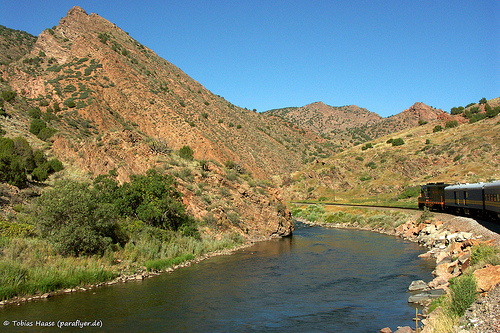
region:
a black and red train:
[407, 180, 449, 213]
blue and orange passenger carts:
[442, 183, 497, 213]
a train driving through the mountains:
[378, 175, 496, 220]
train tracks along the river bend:
[158, 190, 436, 330]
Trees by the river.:
[30, 158, 189, 260]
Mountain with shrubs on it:
[15, 5, 272, 171]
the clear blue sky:
[241, 20, 367, 78]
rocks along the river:
[404, 220, 482, 292]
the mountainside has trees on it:
[92, 53, 249, 203]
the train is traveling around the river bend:
[407, 175, 497, 230]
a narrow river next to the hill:
[23, 222, 431, 331]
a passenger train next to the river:
[415, 178, 499, 223]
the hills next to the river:
[5, 13, 446, 285]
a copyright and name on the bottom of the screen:
[1, 315, 111, 332]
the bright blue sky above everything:
[1, 0, 499, 111]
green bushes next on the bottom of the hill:
[3, 134, 198, 261]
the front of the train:
[414, 183, 449, 209]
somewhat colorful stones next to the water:
[416, 220, 494, 305]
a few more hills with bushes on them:
[283, 99, 490, 181]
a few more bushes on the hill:
[446, 96, 491, 123]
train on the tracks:
[412, 172, 499, 217]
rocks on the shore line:
[115, 264, 159, 285]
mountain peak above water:
[37, 1, 153, 53]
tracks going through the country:
[320, 194, 379, 214]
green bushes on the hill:
[370, 135, 414, 159]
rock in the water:
[403, 278, 429, 293]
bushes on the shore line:
[309, 209, 339, 222]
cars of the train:
[443, 181, 498, 215]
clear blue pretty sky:
[248, 58, 293, 74]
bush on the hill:
[176, 137, 196, 167]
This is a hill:
[33, 5, 170, 118]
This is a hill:
[255, 83, 383, 158]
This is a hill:
[386, 88, 448, 150]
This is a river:
[89, 199, 433, 325]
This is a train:
[411, 177, 498, 219]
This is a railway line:
[279, 189, 419, 221]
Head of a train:
[396, 178, 446, 214]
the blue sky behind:
[140, 0, 475, 101]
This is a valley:
[246, 105, 419, 244]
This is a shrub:
[30, 131, 220, 267]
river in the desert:
[3, 208, 427, 328]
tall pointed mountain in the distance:
[0, 8, 292, 195]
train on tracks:
[420, 182, 499, 222]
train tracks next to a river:
[285, 199, 498, 254]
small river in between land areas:
[0, 207, 439, 328]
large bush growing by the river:
[34, 167, 196, 256]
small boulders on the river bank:
[381, 243, 443, 330]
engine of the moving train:
[421, 181, 448, 208]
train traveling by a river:
[411, 181, 498, 233]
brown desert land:
[3, 6, 498, 206]